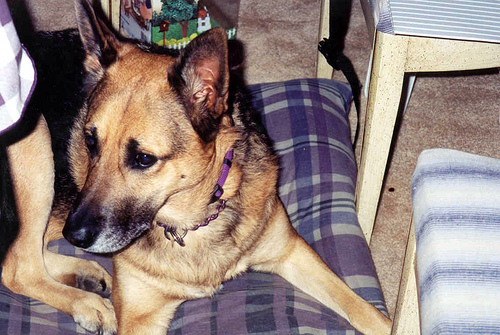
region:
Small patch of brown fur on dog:
[240, 227, 303, 265]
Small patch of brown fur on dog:
[283, 251, 311, 271]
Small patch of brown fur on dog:
[305, 268, 346, 308]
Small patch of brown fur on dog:
[149, 261, 181, 289]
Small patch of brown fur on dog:
[217, 215, 256, 235]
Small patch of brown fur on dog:
[240, 177, 277, 222]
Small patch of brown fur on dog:
[140, 238, 170, 279]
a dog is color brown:
[50, 0, 397, 332]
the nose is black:
[54, 208, 101, 255]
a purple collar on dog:
[201, 139, 243, 213]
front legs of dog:
[99, 255, 399, 333]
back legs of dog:
[0, 175, 115, 332]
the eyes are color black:
[80, 122, 165, 172]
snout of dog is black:
[54, 177, 159, 259]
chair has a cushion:
[376, 142, 498, 333]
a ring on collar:
[159, 212, 195, 252]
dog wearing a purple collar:
[206, 142, 241, 207]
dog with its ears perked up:
[63, 0, 232, 132]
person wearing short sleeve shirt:
[1, 0, 41, 140]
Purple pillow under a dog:
[246, 73, 392, 332]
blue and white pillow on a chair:
[411, 174, 498, 333]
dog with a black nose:
[63, 178, 150, 263]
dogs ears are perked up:
[166, 25, 233, 150]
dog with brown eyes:
[74, 128, 176, 178]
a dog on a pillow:
[32, 38, 332, 325]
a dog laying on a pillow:
[62, 93, 340, 333]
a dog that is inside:
[71, 46, 296, 293]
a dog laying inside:
[22, 62, 283, 323]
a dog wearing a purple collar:
[97, 69, 325, 328]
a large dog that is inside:
[35, 57, 328, 299]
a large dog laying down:
[54, 76, 348, 328]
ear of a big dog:
[169, 23, 231, 144]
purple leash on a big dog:
[208, 141, 238, 216]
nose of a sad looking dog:
[49, 206, 109, 243]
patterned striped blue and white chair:
[410, 135, 499, 327]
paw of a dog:
[70, 287, 114, 334]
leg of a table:
[355, 20, 405, 260]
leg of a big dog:
[272, 245, 407, 331]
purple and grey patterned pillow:
[227, 300, 302, 330]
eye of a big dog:
[126, 141, 176, 178]